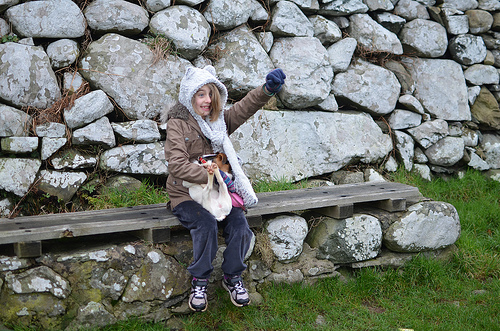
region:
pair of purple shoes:
[175, 261, 265, 319]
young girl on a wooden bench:
[155, 54, 295, 316]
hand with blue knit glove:
[256, 60, 296, 102]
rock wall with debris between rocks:
[295, 14, 494, 152]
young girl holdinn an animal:
[159, 51, 295, 311]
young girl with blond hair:
[170, 54, 252, 151]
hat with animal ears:
[172, 54, 257, 145]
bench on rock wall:
[10, 189, 168, 305]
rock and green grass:
[426, 176, 483, 303]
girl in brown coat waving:
[160, 43, 289, 219]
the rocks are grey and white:
[113, 83, 223, 188]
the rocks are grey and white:
[90, 19, 327, 272]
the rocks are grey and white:
[118, 65, 413, 325]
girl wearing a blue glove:
[179, 56, 298, 136]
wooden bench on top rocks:
[274, 173, 417, 220]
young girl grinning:
[189, 77, 229, 124]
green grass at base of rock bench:
[304, 264, 439, 304]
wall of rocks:
[286, 5, 448, 148]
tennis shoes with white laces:
[182, 265, 259, 315]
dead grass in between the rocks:
[19, 71, 116, 145]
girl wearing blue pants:
[169, 199, 257, 279]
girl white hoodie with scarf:
[176, 63, 233, 145]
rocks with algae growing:
[14, 260, 168, 318]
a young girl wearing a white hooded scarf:
[168, 62, 239, 125]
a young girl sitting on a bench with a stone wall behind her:
[137, 61, 296, 311]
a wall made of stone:
[305, 9, 497, 166]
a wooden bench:
[2, 210, 142, 250]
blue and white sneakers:
[177, 280, 278, 314]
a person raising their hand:
[245, 65, 296, 135]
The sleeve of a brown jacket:
[160, 96, 198, 212]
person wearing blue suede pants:
[164, 202, 291, 277]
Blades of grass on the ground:
[397, 257, 494, 312]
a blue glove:
[263, 66, 294, 101]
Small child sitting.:
[154, 62, 285, 311]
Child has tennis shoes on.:
[183, 278, 255, 320]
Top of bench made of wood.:
[1, 178, 434, 260]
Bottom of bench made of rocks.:
[1, 202, 463, 328]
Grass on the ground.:
[10, 166, 496, 328]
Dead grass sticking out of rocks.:
[18, 29, 223, 148]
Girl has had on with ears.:
[176, 62, 267, 208]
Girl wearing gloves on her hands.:
[208, 66, 286, 191]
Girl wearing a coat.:
[161, 76, 277, 206]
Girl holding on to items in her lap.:
[180, 147, 256, 224]